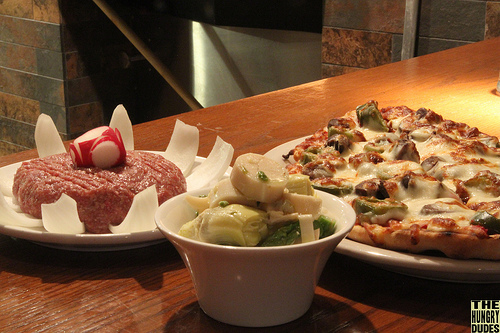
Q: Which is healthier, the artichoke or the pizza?
A: The artichoke is healthier than the pizza.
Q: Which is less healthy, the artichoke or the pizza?
A: The pizza is less healthy than the artichoke.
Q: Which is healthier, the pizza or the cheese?
A: The cheese is healthier than the pizza.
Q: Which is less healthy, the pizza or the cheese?
A: The pizza is less healthy than the cheese.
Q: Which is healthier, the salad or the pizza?
A: The salad is healthier than the pizza.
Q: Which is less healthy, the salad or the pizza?
A: The pizza is less healthy than the salad.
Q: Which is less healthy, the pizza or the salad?
A: The pizza is less healthy than the salad.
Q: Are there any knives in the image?
A: No, there are no knives.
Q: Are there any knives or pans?
A: No, there are no knives or pans.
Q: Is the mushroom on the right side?
A: Yes, the mushroom is on the right of the image.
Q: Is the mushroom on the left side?
A: No, the mushroom is on the right of the image.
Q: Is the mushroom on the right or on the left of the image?
A: The mushroom is on the right of the image.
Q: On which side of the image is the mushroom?
A: The mushroom is on the right of the image.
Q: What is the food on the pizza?
A: The food is a mushroom.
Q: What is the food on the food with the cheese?
A: The food is a mushroom.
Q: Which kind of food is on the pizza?
A: The food is a mushroom.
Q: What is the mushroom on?
A: The mushroom is on the pizza.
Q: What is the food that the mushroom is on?
A: The food is a pizza.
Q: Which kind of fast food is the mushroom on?
A: The mushroom is on the pizza.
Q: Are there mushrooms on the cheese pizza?
A: Yes, there is a mushroom on the pizza.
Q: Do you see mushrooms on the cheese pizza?
A: Yes, there is a mushroom on the pizza.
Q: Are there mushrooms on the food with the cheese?
A: Yes, there is a mushroom on the pizza.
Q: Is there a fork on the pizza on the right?
A: No, there is a mushroom on the pizza.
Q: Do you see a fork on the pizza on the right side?
A: No, there is a mushroom on the pizza.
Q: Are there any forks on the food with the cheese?
A: No, there is a mushroom on the pizza.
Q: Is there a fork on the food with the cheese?
A: No, there is a mushroom on the pizza.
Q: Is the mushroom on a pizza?
A: Yes, the mushroom is on a pizza.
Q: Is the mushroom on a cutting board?
A: No, the mushroom is on a pizza.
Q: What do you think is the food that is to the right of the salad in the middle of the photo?
A: The food is a mushroom.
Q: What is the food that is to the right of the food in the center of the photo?
A: The food is a mushroom.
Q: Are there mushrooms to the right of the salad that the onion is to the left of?
A: Yes, there is a mushroom to the right of the salad.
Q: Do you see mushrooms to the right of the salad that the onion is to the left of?
A: Yes, there is a mushroom to the right of the salad.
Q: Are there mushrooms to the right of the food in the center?
A: Yes, there is a mushroom to the right of the salad.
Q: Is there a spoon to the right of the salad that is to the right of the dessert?
A: No, there is a mushroom to the right of the salad.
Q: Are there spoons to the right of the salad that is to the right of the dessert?
A: No, there is a mushroom to the right of the salad.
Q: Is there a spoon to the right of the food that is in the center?
A: No, there is a mushroom to the right of the salad.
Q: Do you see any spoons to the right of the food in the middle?
A: No, there is a mushroom to the right of the salad.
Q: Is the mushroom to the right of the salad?
A: Yes, the mushroom is to the right of the salad.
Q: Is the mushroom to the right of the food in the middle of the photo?
A: Yes, the mushroom is to the right of the salad.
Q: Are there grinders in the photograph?
A: No, there are no grinders.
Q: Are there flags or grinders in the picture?
A: No, there are no grinders or flags.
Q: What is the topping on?
A: The topping is on the pizza.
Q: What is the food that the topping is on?
A: The food is a pizza.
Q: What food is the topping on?
A: The topping is on the pizza.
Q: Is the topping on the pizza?
A: Yes, the topping is on the pizza.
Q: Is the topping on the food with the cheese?
A: Yes, the topping is on the pizza.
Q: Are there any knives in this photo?
A: No, there are no knives.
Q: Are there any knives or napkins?
A: No, there are no knives or napkins.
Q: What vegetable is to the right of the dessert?
A: The vegetable is an artichoke.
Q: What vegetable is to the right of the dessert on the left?
A: The vegetable is an artichoke.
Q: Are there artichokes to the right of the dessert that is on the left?
A: Yes, there is an artichoke to the right of the dessert.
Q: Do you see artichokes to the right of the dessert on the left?
A: Yes, there is an artichoke to the right of the dessert.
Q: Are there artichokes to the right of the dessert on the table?
A: Yes, there is an artichoke to the right of the dessert.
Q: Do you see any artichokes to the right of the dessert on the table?
A: Yes, there is an artichoke to the right of the dessert.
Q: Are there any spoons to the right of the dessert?
A: No, there is an artichoke to the right of the dessert.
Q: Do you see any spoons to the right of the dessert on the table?
A: No, there is an artichoke to the right of the dessert.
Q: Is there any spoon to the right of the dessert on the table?
A: No, there is an artichoke to the right of the dessert.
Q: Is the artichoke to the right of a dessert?
A: Yes, the artichoke is to the right of a dessert.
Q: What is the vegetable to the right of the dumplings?
A: The vegetable is an artichoke.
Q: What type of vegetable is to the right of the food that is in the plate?
A: The vegetable is an artichoke.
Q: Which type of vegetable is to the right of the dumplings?
A: The vegetable is an artichoke.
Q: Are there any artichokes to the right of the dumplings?
A: Yes, there is an artichoke to the right of the dumplings.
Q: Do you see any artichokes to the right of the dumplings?
A: Yes, there is an artichoke to the right of the dumplings.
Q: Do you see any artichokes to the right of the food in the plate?
A: Yes, there is an artichoke to the right of the dumplings.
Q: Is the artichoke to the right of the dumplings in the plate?
A: Yes, the artichoke is to the right of the dumplings.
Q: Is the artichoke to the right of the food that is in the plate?
A: Yes, the artichoke is to the right of the dumplings.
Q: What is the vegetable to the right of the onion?
A: The vegetable is an artichoke.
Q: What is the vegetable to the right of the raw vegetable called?
A: The vegetable is an artichoke.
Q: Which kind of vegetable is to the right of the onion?
A: The vegetable is an artichoke.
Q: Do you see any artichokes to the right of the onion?
A: Yes, there is an artichoke to the right of the onion.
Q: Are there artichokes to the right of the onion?
A: Yes, there is an artichoke to the right of the onion.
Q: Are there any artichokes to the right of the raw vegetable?
A: Yes, there is an artichoke to the right of the onion.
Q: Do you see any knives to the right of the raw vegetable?
A: No, there is an artichoke to the right of the onion.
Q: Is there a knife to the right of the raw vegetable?
A: No, there is an artichoke to the right of the onion.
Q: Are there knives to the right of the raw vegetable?
A: No, there is an artichoke to the right of the onion.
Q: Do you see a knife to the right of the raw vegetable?
A: No, there is an artichoke to the right of the onion.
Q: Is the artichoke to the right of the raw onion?
A: Yes, the artichoke is to the right of the onion.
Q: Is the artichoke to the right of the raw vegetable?
A: Yes, the artichoke is to the right of the onion.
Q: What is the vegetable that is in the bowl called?
A: The vegetable is an artichoke.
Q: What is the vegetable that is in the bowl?
A: The vegetable is an artichoke.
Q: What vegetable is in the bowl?
A: The vegetable is an artichoke.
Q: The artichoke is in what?
A: The artichoke is in the bowl.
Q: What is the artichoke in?
A: The artichoke is in the bowl.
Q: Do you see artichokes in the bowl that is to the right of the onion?
A: Yes, there is an artichoke in the bowl.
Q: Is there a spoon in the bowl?
A: No, there is an artichoke in the bowl.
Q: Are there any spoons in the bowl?
A: No, there is an artichoke in the bowl.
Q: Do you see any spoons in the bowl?
A: No, there is an artichoke in the bowl.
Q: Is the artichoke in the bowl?
A: Yes, the artichoke is in the bowl.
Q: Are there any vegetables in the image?
A: Yes, there are vegetables.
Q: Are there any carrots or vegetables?
A: Yes, there are vegetables.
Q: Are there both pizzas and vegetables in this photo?
A: Yes, there are both vegetables and a pizza.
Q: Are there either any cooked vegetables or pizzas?
A: Yes, there are cooked vegetables.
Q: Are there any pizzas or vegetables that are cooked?
A: Yes, the vegetables are cooked.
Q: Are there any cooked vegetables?
A: Yes, there are cooked vegetables.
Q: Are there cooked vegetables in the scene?
A: Yes, there are cooked vegetables.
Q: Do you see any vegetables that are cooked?
A: Yes, there are vegetables that are cooked.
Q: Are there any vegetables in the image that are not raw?
A: Yes, there are cooked vegetables.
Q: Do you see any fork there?
A: No, there are no forks.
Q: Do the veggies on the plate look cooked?
A: Yes, the veggies are cooked.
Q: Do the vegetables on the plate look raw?
A: No, the vegetables are cooked.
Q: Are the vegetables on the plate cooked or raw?
A: The vegetables are cooked.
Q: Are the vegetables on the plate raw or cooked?
A: The vegetables are cooked.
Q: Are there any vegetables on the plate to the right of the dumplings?
A: Yes, there are vegetables on the plate.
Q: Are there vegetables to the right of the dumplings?
A: Yes, there are vegetables to the right of the dumplings.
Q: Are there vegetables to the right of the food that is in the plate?
A: Yes, there are vegetables to the right of the dumplings.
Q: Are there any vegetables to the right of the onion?
A: Yes, there are vegetables to the right of the onion.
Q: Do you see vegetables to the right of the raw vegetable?
A: Yes, there are vegetables to the right of the onion.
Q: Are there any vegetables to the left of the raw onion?
A: No, the vegetables are to the right of the onion.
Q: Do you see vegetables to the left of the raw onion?
A: No, the vegetables are to the right of the onion.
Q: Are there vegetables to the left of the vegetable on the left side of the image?
A: No, the vegetables are to the right of the onion.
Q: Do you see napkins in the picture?
A: No, there are no napkins.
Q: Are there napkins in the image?
A: No, there are no napkins.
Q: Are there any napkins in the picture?
A: No, there are no napkins.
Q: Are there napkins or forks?
A: No, there are no napkins or forks.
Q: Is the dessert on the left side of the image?
A: Yes, the dessert is on the left of the image.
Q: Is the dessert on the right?
A: No, the dessert is on the left of the image.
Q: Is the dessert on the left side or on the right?
A: The dessert is on the left of the image.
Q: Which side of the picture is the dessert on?
A: The dessert is on the left of the image.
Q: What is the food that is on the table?
A: The food is a dessert.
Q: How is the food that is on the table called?
A: The food is a dessert.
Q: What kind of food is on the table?
A: The food is a dessert.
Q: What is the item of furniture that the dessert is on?
A: The piece of furniture is a table.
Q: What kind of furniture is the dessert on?
A: The dessert is on the table.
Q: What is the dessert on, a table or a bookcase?
A: The dessert is on a table.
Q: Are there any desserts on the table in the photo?
A: Yes, there is a dessert on the table.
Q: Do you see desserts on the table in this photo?
A: Yes, there is a dessert on the table.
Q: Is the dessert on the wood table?
A: Yes, the dessert is on the table.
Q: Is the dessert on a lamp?
A: No, the dessert is on the table.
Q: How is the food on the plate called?
A: The food is a dessert.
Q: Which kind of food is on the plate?
A: The food is a dessert.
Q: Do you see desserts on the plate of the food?
A: Yes, there is a dessert on the plate.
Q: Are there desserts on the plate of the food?
A: Yes, there is a dessert on the plate.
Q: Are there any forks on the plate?
A: No, there is a dessert on the plate.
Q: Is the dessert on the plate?
A: Yes, the dessert is on the plate.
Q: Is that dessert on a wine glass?
A: No, the dessert is on the plate.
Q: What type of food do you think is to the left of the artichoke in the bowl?
A: The food is a dessert.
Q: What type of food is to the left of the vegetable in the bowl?
A: The food is a dessert.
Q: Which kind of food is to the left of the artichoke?
A: The food is a dessert.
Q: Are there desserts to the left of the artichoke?
A: Yes, there is a dessert to the left of the artichoke.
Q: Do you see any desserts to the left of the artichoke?
A: Yes, there is a dessert to the left of the artichoke.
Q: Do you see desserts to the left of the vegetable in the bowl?
A: Yes, there is a dessert to the left of the artichoke.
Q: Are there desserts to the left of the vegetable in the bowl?
A: Yes, there is a dessert to the left of the artichoke.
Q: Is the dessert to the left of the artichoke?
A: Yes, the dessert is to the left of the artichoke.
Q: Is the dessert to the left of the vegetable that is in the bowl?
A: Yes, the dessert is to the left of the artichoke.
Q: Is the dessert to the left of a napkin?
A: No, the dessert is to the left of the artichoke.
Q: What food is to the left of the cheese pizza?
A: The food is a dessert.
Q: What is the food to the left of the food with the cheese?
A: The food is a dessert.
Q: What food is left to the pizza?
A: The food is a dessert.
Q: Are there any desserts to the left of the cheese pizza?
A: Yes, there is a dessert to the left of the pizza.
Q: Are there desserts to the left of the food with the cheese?
A: Yes, there is a dessert to the left of the pizza.